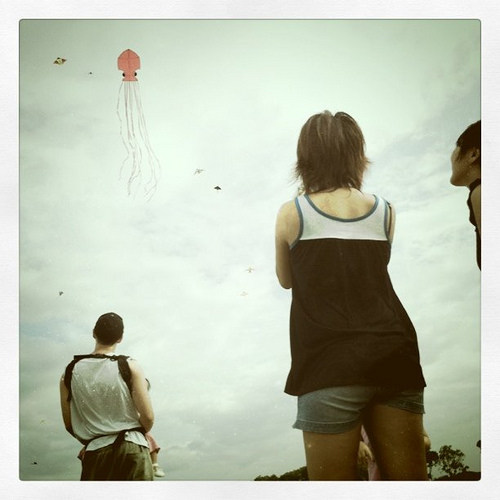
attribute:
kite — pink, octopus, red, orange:
[116, 48, 162, 200]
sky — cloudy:
[18, 18, 482, 482]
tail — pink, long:
[119, 81, 162, 200]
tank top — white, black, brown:
[282, 189, 428, 397]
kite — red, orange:
[54, 56, 69, 66]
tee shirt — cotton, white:
[63, 353, 155, 452]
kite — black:
[215, 185, 222, 191]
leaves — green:
[439, 444, 473, 478]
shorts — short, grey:
[292, 384, 426, 433]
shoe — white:
[152, 463, 164, 477]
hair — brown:
[294, 110, 373, 194]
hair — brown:
[457, 120, 482, 163]